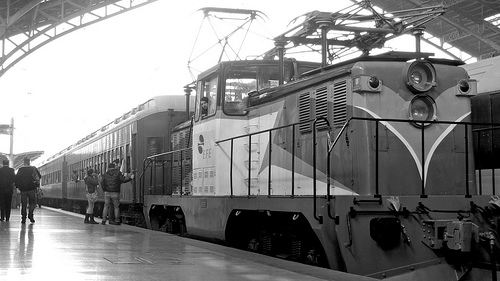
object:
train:
[140, 49, 478, 267]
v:
[351, 104, 473, 189]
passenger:
[199, 97, 209, 118]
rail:
[267, 129, 272, 196]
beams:
[190, 6, 269, 63]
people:
[99, 162, 137, 226]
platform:
[86, 247, 210, 278]